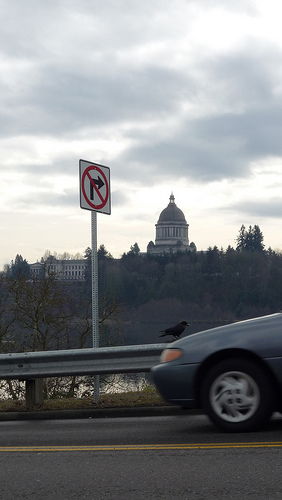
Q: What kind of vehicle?
A: Car.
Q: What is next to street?
A: Railing.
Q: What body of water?
A: River.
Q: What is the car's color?
A: Grey.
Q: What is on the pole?
A: A sign.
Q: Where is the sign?
A: On the pole.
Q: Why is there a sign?
A: To direct drivers.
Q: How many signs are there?
A: One.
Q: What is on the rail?
A: A bird.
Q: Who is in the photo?
A: Nobody.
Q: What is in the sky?
A: Clouds.